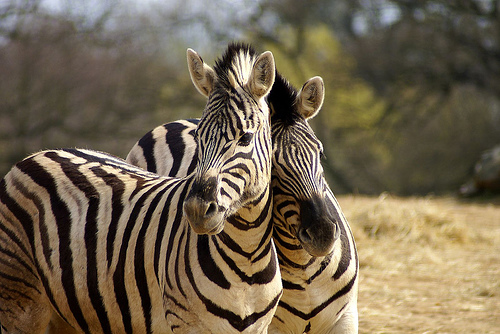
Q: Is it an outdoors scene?
A: Yes, it is outdoors.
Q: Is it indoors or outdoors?
A: It is outdoors.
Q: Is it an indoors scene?
A: No, it is outdoors.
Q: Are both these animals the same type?
A: Yes, all the animals are zebras.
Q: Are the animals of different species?
A: No, all the animals are zebras.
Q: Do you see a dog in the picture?
A: No, there are no dogs.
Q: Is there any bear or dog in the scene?
A: No, there are no dogs or bears.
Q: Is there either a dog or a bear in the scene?
A: No, there are no dogs or bears.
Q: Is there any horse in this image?
A: No, there are no horses.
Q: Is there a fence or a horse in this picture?
A: No, there are no horses or fences.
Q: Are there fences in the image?
A: No, there are no fences.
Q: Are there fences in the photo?
A: No, there are no fences.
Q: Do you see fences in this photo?
A: No, there are no fences.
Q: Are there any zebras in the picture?
A: Yes, there is a zebra.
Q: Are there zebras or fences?
A: Yes, there is a zebra.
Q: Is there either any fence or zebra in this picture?
A: Yes, there is a zebra.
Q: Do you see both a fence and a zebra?
A: No, there is a zebra but no fences.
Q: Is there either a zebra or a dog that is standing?
A: Yes, the zebra is standing.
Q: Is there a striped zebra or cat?
A: Yes, there is a striped zebra.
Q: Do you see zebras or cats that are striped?
A: Yes, the zebra is striped.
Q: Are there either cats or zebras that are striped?
A: Yes, the zebra is striped.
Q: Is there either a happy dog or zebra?
A: Yes, there is a happy zebra.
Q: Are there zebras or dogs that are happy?
A: Yes, the zebra is happy.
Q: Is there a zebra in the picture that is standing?
A: Yes, there is a zebra that is standing.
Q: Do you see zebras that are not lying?
A: Yes, there is a zebra that is standing .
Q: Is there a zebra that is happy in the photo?
A: Yes, there is a happy zebra.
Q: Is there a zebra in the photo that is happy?
A: Yes, there is a zebra that is happy.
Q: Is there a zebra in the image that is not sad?
A: Yes, there is a happy zebra.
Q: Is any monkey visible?
A: No, there are no monkeys.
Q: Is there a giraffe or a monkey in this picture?
A: No, there are no monkeys or giraffes.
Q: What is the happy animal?
A: The animal is a zebra.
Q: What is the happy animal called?
A: The animal is a zebra.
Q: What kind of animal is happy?
A: The animal is a zebra.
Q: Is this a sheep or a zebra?
A: This is a zebra.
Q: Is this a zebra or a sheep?
A: This is a zebra.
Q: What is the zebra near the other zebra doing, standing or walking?
A: The zebra is standing.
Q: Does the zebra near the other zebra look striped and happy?
A: Yes, the zebra is striped and happy.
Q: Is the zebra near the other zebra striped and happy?
A: Yes, the zebra is striped and happy.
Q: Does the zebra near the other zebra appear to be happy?
A: Yes, the zebra is happy.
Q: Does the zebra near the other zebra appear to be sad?
A: No, the zebra is happy.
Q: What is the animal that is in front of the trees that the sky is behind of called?
A: The animal is a zebra.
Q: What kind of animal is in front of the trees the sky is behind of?
A: The animal is a zebra.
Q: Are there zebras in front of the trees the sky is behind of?
A: Yes, there is a zebra in front of the trees.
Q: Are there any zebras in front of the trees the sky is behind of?
A: Yes, there is a zebra in front of the trees.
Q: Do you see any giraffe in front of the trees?
A: No, there is a zebra in front of the trees.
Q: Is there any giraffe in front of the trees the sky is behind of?
A: No, there is a zebra in front of the trees.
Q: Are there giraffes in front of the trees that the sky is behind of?
A: No, there is a zebra in front of the trees.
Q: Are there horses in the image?
A: No, there are no horses.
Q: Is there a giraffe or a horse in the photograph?
A: No, there are no horses or giraffes.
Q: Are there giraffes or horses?
A: No, there are no horses or giraffes.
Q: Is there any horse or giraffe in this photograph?
A: No, there are no horses or giraffes.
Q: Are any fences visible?
A: No, there are no fences.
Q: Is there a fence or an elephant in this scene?
A: No, there are no fences or elephants.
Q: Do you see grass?
A: Yes, there is grass.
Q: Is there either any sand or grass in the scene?
A: Yes, there is grass.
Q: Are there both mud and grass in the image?
A: No, there is grass but no mud.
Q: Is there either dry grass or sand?
A: Yes, there is dry grass.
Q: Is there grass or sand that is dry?
A: Yes, the grass is dry.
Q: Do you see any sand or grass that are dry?
A: Yes, the grass is dry.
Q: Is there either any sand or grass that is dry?
A: Yes, the grass is dry.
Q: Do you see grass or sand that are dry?
A: Yes, the grass is dry.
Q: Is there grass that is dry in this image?
A: Yes, there is dry grass.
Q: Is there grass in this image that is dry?
A: Yes, there is grass that is dry.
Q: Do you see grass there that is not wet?
A: Yes, there is dry grass.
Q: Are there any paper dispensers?
A: No, there are no paper dispensers.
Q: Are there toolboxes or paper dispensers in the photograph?
A: No, there are no paper dispensers or toolboxes.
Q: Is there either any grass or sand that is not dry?
A: No, there is grass but it is dry.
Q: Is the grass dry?
A: Yes, the grass is dry.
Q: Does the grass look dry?
A: Yes, the grass is dry.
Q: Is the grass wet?
A: No, the grass is dry.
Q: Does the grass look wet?
A: No, the grass is dry.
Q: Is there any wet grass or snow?
A: No, there is grass but it is dry.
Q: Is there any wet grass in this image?
A: No, there is grass but it is dry.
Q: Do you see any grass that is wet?
A: No, there is grass but it is dry.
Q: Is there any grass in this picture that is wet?
A: No, there is grass but it is dry.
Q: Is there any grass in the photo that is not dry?
A: No, there is grass but it is dry.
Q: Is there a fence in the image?
A: No, there are no fences.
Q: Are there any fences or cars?
A: No, there are no fences or cars.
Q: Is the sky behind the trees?
A: Yes, the sky is behind the trees.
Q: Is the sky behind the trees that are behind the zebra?
A: Yes, the sky is behind the trees.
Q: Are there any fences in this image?
A: No, there are no fences.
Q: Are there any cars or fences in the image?
A: No, there are no fences or cars.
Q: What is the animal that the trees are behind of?
A: The animal is a zebra.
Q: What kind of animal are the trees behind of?
A: The trees are behind the zebra.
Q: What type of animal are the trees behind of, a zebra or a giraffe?
A: The trees are behind a zebra.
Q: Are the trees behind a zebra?
A: Yes, the trees are behind a zebra.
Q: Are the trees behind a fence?
A: No, the trees are behind a zebra.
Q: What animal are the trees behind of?
A: The trees are behind the zebra.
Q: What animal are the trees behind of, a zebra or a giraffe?
A: The trees are behind a zebra.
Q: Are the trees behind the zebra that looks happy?
A: Yes, the trees are behind the zebra.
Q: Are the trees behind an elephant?
A: No, the trees are behind the zebra.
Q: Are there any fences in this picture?
A: No, there are no fences.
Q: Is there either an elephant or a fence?
A: No, there are no fences or elephants.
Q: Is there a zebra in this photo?
A: Yes, there is a zebra.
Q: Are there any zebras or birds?
A: Yes, there is a zebra.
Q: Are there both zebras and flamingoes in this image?
A: No, there is a zebra but no flamingoes.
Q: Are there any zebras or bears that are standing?
A: Yes, the zebra is standing.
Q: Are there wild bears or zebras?
A: Yes, there is a wild zebra.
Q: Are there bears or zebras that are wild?
A: Yes, the zebra is wild.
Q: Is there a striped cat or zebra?
A: Yes, there is a striped zebra.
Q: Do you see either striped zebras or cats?
A: Yes, there is a striped zebra.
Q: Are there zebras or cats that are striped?
A: Yes, the zebra is striped.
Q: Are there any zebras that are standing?
A: Yes, there is a zebra that is standing.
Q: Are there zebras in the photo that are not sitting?
A: Yes, there is a zebra that is standing.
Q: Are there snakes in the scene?
A: No, there are no snakes.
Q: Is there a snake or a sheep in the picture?
A: No, there are no snakes or sheep.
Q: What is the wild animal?
A: The animal is a zebra.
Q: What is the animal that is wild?
A: The animal is a zebra.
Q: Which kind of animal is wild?
A: The animal is a zebra.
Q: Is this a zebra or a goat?
A: This is a zebra.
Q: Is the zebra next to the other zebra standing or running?
A: The zebra is standing.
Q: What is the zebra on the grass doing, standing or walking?
A: The zebra is standing.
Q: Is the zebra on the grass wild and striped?
A: Yes, the zebra is wild and striped.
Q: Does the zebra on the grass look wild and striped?
A: Yes, the zebra is wild and striped.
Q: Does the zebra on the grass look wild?
A: Yes, the zebra is wild.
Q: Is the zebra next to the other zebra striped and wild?
A: Yes, the zebra is striped and wild.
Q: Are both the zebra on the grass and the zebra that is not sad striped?
A: Yes, both the zebra and the zebra are striped.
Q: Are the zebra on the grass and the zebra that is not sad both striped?
A: Yes, both the zebra and the zebra are striped.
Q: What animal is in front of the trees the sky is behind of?
A: The zebra is in front of the trees.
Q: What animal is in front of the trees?
A: The zebra is in front of the trees.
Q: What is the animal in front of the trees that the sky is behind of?
A: The animal is a zebra.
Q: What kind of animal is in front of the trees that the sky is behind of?
A: The animal is a zebra.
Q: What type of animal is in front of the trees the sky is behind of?
A: The animal is a zebra.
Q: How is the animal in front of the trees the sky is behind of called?
A: The animal is a zebra.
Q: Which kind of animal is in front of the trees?
A: The animal is a zebra.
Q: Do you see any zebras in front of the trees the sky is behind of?
A: Yes, there is a zebra in front of the trees.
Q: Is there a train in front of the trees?
A: No, there is a zebra in front of the trees.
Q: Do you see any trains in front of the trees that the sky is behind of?
A: No, there is a zebra in front of the trees.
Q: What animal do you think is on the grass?
A: The zebra is on the grass.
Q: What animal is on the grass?
A: The zebra is on the grass.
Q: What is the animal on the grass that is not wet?
A: The animal is a zebra.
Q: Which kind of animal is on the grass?
A: The animal is a zebra.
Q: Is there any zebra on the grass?
A: Yes, there is a zebra on the grass.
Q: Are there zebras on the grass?
A: Yes, there is a zebra on the grass.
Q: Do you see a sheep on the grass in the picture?
A: No, there is a zebra on the grass.